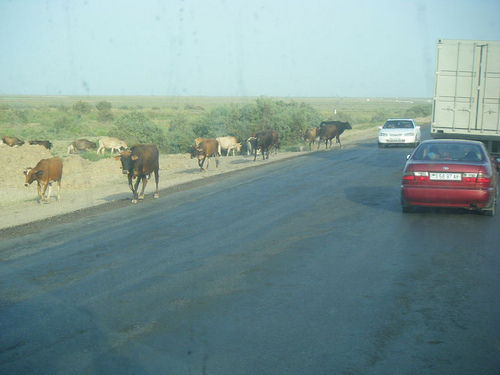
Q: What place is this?
A: It is a highway.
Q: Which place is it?
A: It is a highway.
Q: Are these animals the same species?
A: Yes, all the animals are cows.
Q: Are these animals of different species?
A: No, all the animals are cows.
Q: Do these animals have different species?
A: No, all the animals are cows.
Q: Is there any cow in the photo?
A: Yes, there is a cow.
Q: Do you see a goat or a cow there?
A: Yes, there is a cow.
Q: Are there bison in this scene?
A: No, there are no bison.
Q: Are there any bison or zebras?
A: No, there are no bison or zebras.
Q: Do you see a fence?
A: No, there are no fences.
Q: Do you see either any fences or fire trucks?
A: No, there are no fences or fire trucks.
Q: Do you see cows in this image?
A: Yes, there is a cow.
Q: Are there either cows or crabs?
A: Yes, there is a cow.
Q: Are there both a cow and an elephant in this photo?
A: No, there is a cow but no elephants.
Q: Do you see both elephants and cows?
A: No, there is a cow but no elephants.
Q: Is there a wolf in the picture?
A: No, there are no wolves.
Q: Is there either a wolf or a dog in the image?
A: No, there are no wolves or dogs.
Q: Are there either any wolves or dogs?
A: No, there are no wolves or dogs.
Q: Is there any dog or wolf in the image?
A: No, there are no wolves or dogs.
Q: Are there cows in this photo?
A: Yes, there is a cow.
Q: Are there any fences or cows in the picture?
A: Yes, there is a cow.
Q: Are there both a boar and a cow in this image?
A: No, there is a cow but no boars.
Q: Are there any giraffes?
A: No, there are no giraffes.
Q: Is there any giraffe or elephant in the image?
A: No, there are no giraffes or elephants.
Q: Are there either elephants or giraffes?
A: No, there are no giraffes or elephants.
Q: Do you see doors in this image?
A: Yes, there are doors.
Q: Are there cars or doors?
A: Yes, there are doors.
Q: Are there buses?
A: No, there are no buses.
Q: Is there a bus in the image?
A: No, there are no buses.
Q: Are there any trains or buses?
A: No, there are no buses or trains.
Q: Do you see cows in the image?
A: Yes, there is a cow.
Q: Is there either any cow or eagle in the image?
A: Yes, there is a cow.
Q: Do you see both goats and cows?
A: No, there is a cow but no goats.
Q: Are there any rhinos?
A: No, there are no rhinos.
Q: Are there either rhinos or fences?
A: No, there are no rhinos or fences.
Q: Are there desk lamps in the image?
A: No, there are no desk lamps.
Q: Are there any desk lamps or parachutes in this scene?
A: No, there are no desk lamps or parachutes.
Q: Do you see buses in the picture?
A: No, there are no buses.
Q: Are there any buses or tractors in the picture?
A: No, there are no buses or tractors.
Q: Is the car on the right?
A: Yes, the car is on the right of the image.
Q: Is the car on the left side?
A: No, the car is on the right of the image.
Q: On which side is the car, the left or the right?
A: The car is on the right of the image.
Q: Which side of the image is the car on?
A: The car is on the right of the image.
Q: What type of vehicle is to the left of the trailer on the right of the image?
A: The vehicle is a car.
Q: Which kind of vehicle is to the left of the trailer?
A: The vehicle is a car.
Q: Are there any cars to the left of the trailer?
A: Yes, there is a car to the left of the trailer.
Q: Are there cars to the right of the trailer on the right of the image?
A: No, the car is to the left of the trailer.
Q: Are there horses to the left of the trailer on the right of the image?
A: No, there is a car to the left of the trailer.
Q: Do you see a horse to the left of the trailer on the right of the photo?
A: No, there is a car to the left of the trailer.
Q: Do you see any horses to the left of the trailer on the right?
A: No, there is a car to the left of the trailer.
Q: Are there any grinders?
A: No, there are no grinders.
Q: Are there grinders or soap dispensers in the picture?
A: No, there are no grinders or soap dispensers.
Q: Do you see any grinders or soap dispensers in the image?
A: No, there are no grinders or soap dispensers.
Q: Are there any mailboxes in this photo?
A: No, there are no mailboxes.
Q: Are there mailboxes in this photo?
A: No, there are no mailboxes.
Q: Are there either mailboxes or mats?
A: No, there are no mailboxes or mats.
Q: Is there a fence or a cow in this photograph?
A: Yes, there is a cow.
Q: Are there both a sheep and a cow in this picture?
A: No, there is a cow but no sheep.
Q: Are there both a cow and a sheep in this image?
A: No, there is a cow but no sheep.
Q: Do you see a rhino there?
A: No, there are no rhinos.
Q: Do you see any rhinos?
A: No, there are no rhinos.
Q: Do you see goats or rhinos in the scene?
A: No, there are no rhinos or goats.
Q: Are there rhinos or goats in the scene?
A: No, there are no rhinos or goats.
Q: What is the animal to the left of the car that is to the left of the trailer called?
A: The animal is a cow.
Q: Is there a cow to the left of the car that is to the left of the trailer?
A: Yes, there is a cow to the left of the car.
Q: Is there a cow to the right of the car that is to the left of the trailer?
A: No, the cow is to the left of the car.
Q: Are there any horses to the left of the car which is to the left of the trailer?
A: No, there is a cow to the left of the car.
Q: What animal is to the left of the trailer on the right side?
A: The animal is a cow.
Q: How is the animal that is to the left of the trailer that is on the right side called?
A: The animal is a cow.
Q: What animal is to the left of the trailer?
A: The animal is a cow.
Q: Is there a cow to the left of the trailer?
A: Yes, there is a cow to the left of the trailer.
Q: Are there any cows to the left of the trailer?
A: Yes, there is a cow to the left of the trailer.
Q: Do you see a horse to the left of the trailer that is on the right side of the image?
A: No, there is a cow to the left of the trailer.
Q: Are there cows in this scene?
A: Yes, there is a cow.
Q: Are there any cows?
A: Yes, there is a cow.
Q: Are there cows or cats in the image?
A: Yes, there is a cow.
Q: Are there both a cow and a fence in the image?
A: No, there is a cow but no fences.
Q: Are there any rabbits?
A: No, there are no rabbits.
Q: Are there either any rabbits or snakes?
A: No, there are no rabbits or snakes.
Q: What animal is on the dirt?
A: The cow is on the dirt.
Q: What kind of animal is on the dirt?
A: The animal is a cow.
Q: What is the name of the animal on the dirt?
A: The animal is a cow.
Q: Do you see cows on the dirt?
A: Yes, there is a cow on the dirt.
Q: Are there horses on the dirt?
A: No, there is a cow on the dirt.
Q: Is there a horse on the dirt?
A: No, there is a cow on the dirt.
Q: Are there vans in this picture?
A: No, there are no vans.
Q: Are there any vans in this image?
A: No, there are no vans.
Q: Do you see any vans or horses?
A: No, there are no vans or horses.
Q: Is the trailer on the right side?
A: Yes, the trailer is on the right of the image.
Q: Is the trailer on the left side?
A: No, the trailer is on the right of the image.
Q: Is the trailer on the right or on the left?
A: The trailer is on the right of the image.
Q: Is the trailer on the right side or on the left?
A: The trailer is on the right of the image.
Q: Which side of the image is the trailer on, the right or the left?
A: The trailer is on the right of the image.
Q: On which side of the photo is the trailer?
A: The trailer is on the right of the image.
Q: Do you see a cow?
A: Yes, there is a cow.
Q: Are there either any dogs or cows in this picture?
A: Yes, there is a cow.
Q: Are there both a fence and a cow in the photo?
A: No, there is a cow but no fences.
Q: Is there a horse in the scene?
A: No, there are no horses.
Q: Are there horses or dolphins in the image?
A: No, there are no horses or dolphins.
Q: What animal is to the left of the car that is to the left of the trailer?
A: The animal is a cow.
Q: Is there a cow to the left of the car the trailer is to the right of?
A: Yes, there is a cow to the left of the car.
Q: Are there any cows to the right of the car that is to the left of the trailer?
A: No, the cow is to the left of the car.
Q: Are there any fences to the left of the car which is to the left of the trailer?
A: No, there is a cow to the left of the car.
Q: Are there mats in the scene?
A: No, there are no mats.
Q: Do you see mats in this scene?
A: No, there are no mats.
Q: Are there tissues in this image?
A: No, there are no tissues.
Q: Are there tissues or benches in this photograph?
A: No, there are no tissues or benches.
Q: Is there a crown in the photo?
A: No, there are no crowns.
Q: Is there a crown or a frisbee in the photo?
A: No, there are no crowns or frisbees.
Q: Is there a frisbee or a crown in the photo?
A: No, there are no crowns or frisbees.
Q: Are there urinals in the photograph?
A: No, there are no urinals.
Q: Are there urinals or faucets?
A: No, there are no urinals or faucets.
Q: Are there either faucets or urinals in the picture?
A: No, there are no urinals or faucets.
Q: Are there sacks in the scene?
A: No, there are no sacks.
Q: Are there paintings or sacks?
A: No, there are no sacks or paintings.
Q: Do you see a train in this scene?
A: No, there are no trains.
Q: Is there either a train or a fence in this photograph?
A: No, there are no trains or fences.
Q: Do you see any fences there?
A: No, there are no fences.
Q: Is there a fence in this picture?
A: No, there are no fences.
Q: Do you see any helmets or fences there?
A: No, there are no fences or helmets.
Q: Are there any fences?
A: No, there are no fences.